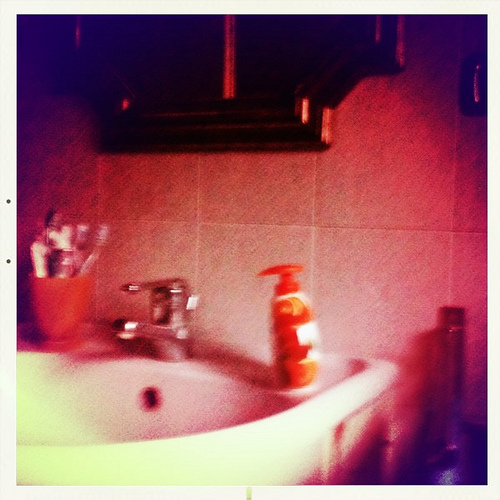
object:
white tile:
[314, 73, 457, 231]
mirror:
[76, 16, 341, 159]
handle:
[119, 277, 188, 297]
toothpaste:
[27, 242, 54, 278]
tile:
[195, 222, 313, 355]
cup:
[29, 272, 95, 343]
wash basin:
[17, 320, 402, 490]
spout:
[249, 264, 305, 283]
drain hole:
[141, 385, 162, 413]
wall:
[16, 13, 486, 421]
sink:
[15, 336, 295, 456]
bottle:
[253, 260, 320, 389]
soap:
[248, 266, 322, 391]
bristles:
[97, 225, 109, 244]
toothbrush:
[74, 223, 109, 278]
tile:
[95, 220, 200, 332]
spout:
[113, 316, 193, 355]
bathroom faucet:
[111, 277, 200, 361]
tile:
[311, 224, 451, 361]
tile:
[95, 153, 199, 221]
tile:
[198, 153, 318, 223]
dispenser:
[256, 261, 323, 389]